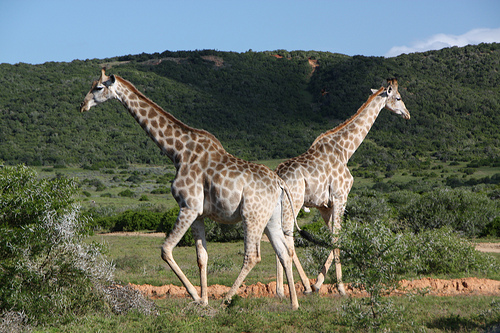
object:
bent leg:
[160, 206, 201, 302]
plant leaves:
[394, 296, 410, 323]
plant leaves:
[414, 200, 433, 210]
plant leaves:
[348, 243, 375, 285]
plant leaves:
[93, 205, 160, 235]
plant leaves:
[117, 189, 136, 197]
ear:
[387, 85, 395, 96]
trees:
[454, 45, 475, 70]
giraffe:
[275, 77, 411, 301]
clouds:
[382, 27, 500, 58]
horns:
[390, 77, 398, 90]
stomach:
[203, 192, 240, 224]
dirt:
[201, 56, 224, 66]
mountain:
[0, 42, 500, 166]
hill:
[8, 91, 92, 162]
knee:
[160, 245, 176, 262]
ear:
[102, 74, 115, 88]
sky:
[0, 0, 500, 63]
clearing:
[91, 47, 348, 73]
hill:
[148, 40, 324, 106]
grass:
[0, 300, 74, 330]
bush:
[295, 210, 497, 302]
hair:
[379, 77, 399, 97]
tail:
[279, 182, 314, 242]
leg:
[219, 188, 274, 308]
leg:
[264, 193, 299, 310]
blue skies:
[5, 8, 54, 58]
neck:
[117, 82, 192, 154]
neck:
[332, 95, 381, 166]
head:
[371, 77, 411, 119]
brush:
[0, 162, 148, 333]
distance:
[1, 0, 500, 90]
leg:
[161, 207, 201, 301]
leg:
[190, 216, 209, 305]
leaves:
[451, 193, 461, 216]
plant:
[392, 183, 421, 227]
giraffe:
[76, 66, 312, 311]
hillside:
[408, 42, 499, 121]